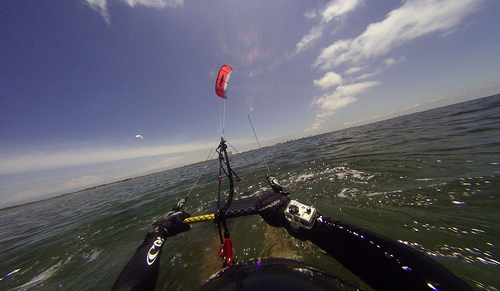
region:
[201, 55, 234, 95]
red and white parachute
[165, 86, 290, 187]
lines holding white and red parachute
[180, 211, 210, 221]
yellow portion of rope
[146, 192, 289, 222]
handles person is holding onto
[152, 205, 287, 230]
black gloves of person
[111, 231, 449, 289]
black arms of wetsuit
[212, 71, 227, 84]
black spot on white and red parachute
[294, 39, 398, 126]
group of clouds in sky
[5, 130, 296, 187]
white hazy clouds in the sky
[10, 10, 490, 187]
bright blue sky above ocean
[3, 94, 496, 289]
greenish colored water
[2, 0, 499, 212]
thin clouds in a blue sky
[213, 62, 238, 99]
red and black kite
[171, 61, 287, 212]
kite attached to ropes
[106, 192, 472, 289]
para-sail harness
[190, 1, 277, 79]
sun rays showing in the sky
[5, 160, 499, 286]
white foam in the water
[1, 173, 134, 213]
land in the distance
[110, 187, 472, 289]
black para-sail harness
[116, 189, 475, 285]
black harness with white writing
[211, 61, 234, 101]
red and white parasail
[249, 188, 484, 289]
person's right arm in black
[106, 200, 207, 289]
person's left arm in black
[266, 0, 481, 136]
white clouds in sky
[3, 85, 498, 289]
green tinted ocean water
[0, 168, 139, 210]
land in distant background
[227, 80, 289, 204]
safety wire attached to parasail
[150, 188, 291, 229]
yellow and black grip handle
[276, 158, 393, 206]
white tops of splashing waves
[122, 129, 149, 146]
distant parasail in sky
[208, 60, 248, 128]
A red sail in the air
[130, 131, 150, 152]
A white sail in the air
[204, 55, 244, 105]
A large sail in the sky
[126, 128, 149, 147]
A sail in the distance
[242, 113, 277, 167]
Wires on a boat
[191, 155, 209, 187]
Wires on a boat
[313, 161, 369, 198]
Waves in the water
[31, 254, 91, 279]
Ripples in the water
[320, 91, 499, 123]
The horizon in the distance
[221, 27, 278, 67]
A light blur in the sky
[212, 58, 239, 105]
red kite in the sky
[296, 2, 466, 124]
white clouds in the sky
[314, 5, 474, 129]
thin white clouds in sky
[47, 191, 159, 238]
calm ocean water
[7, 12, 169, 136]
bright clear blue sky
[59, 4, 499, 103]
bright blue sky with clouds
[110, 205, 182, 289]
arm of a person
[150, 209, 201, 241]
hand wearing a black glove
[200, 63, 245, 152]
red kite attached to white string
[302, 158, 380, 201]
white sea foam